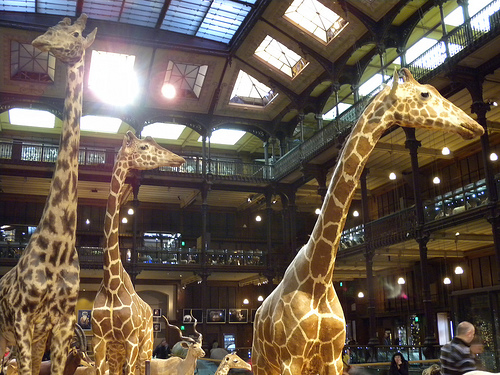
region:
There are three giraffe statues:
[20, 22, 478, 359]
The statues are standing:
[24, 26, 477, 360]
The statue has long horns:
[155, 306, 213, 363]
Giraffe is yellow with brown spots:
[224, 63, 476, 364]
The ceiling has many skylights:
[28, 22, 339, 131]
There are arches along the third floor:
[3, 96, 275, 153]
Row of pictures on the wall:
[165, 292, 258, 329]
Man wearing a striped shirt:
[434, 319, 482, 366]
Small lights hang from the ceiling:
[360, 242, 472, 304]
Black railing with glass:
[137, 169, 482, 279]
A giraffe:
[306, 305, 340, 340]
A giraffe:
[277, 266, 319, 319]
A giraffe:
[308, 279, 324, 339]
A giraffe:
[282, 282, 307, 362]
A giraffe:
[260, 263, 285, 373]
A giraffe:
[279, 271, 288, 315]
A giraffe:
[297, 284, 332, 361]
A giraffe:
[260, 237, 311, 369]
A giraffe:
[290, 317, 307, 365]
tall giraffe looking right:
[251, 51, 486, 373]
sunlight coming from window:
[90, 50, 143, 111]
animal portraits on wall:
[181, 305, 253, 327]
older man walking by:
[436, 310, 498, 373]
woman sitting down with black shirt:
[388, 348, 409, 373]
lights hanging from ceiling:
[433, 258, 473, 290]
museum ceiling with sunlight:
[120, 7, 336, 117]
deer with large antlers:
[155, 310, 210, 372]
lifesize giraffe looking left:
[2, 11, 94, 371]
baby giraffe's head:
[213, 345, 254, 374]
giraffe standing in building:
[250, 64, 482, 366]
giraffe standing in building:
[106, 126, 193, 367]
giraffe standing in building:
[28, 17, 100, 357]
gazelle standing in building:
[155, 312, 212, 373]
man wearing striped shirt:
[438, 317, 487, 369]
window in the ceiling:
[241, 20, 304, 86]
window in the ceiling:
[217, 65, 279, 131]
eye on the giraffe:
[413, 80, 443, 103]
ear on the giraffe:
[377, 59, 404, 94]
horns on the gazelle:
[158, 305, 208, 345]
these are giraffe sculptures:
[3, 19, 464, 374]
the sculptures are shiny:
[274, 297, 336, 360]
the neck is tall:
[53, 58, 97, 268]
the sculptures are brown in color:
[107, 281, 129, 311]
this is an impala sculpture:
[165, 312, 211, 372]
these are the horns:
[161, 310, 207, 343]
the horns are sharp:
[154, 310, 204, 339]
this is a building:
[206, 2, 283, 258]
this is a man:
[440, 320, 479, 363]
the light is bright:
[94, 58, 142, 105]